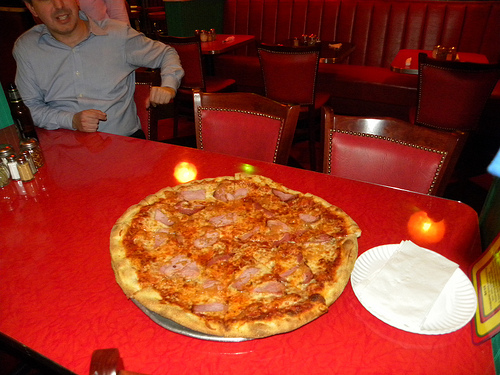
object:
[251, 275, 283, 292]
meat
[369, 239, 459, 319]
napkins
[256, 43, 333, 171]
chair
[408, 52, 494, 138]
chair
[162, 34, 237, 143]
chair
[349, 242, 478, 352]
plate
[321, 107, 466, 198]
chair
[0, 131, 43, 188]
spices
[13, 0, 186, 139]
man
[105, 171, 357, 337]
crust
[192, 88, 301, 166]
chair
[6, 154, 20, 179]
salt shaker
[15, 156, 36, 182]
pepper shaker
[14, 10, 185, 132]
long sleeve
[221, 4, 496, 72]
wall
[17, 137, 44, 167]
pepper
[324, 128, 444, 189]
padding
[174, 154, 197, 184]
light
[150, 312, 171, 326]
plate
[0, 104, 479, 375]
table